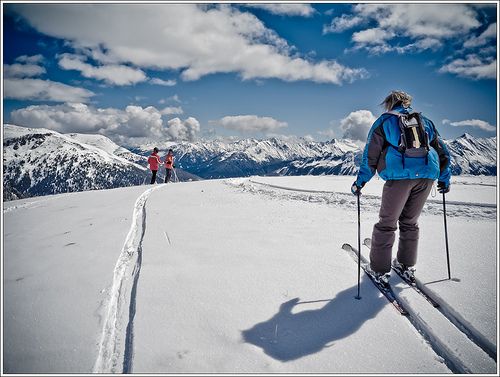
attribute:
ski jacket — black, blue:
[355, 105, 451, 189]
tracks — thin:
[338, 245, 491, 370]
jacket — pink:
[144, 148, 164, 170]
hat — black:
[149, 145, 164, 155]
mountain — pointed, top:
[13, 88, 203, 233]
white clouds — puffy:
[12, 10, 496, 83]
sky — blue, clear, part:
[193, 81, 355, 111]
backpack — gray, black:
[397, 116, 432, 157]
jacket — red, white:
[147, 150, 167, 169]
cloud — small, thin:
[148, 73, 177, 89]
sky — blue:
[5, 3, 495, 145]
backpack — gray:
[394, 109, 433, 160]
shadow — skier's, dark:
[237, 272, 405, 362]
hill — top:
[111, 144, 231, 216]